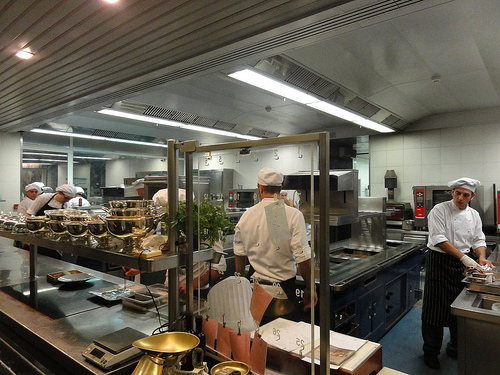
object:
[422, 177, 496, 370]
cook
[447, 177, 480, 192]
hat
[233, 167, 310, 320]
cook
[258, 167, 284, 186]
hat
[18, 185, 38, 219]
cook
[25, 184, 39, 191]
hat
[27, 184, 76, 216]
cook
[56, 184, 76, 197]
hat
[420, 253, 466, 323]
apron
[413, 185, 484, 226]
microwave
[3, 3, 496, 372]
kitchen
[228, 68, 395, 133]
light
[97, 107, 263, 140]
light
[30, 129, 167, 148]
light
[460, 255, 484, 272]
glove